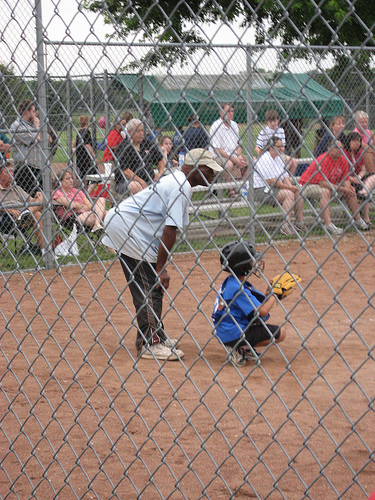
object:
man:
[212, 100, 247, 193]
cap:
[182, 147, 223, 174]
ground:
[199, 243, 221, 291]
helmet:
[219, 239, 264, 278]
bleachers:
[182, 167, 365, 230]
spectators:
[207, 102, 249, 199]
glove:
[263, 271, 303, 301]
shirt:
[301, 152, 351, 187]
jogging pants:
[114, 251, 169, 348]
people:
[70, 109, 103, 175]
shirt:
[211, 273, 269, 343]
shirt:
[97, 169, 194, 265]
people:
[7, 99, 53, 199]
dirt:
[1, 229, 373, 499]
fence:
[17, 23, 374, 383]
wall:
[160, 51, 211, 62]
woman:
[51, 168, 114, 253]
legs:
[76, 205, 114, 230]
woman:
[343, 132, 375, 230]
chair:
[39, 204, 93, 245]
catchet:
[206, 240, 304, 369]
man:
[102, 147, 218, 363]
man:
[0, 160, 48, 253]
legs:
[29, 198, 48, 256]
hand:
[271, 267, 302, 299]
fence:
[3, 1, 373, 498]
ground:
[1, 232, 372, 499]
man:
[299, 140, 368, 235]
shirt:
[206, 115, 241, 164]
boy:
[210, 240, 304, 367]